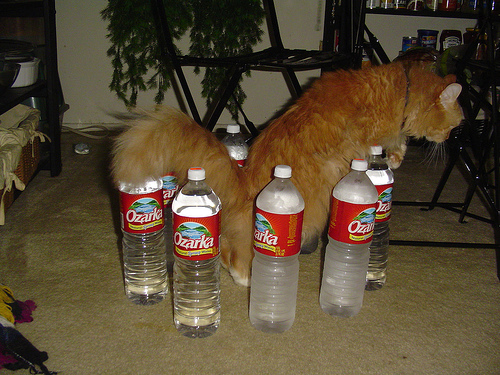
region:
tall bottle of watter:
[321, 158, 378, 320]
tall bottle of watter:
[362, 143, 389, 294]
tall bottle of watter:
[252, 163, 299, 335]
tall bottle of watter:
[169, 165, 226, 338]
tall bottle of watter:
[116, 160, 168, 302]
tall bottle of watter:
[213, 123, 246, 167]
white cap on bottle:
[349, 155, 370, 174]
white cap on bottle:
[271, 162, 295, 180]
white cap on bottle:
[184, 165, 209, 183]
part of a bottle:
[341, 297, 347, 305]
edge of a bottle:
[273, 305, 274, 306]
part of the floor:
[253, 327, 303, 362]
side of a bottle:
[241, 281, 253, 291]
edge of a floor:
[377, 311, 382, 334]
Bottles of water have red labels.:
[159, 155, 384, 346]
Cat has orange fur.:
[101, 44, 496, 295]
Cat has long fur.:
[95, 33, 483, 299]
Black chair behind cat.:
[135, 1, 418, 208]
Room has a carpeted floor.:
[37, 88, 498, 374]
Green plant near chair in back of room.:
[58, 2, 298, 137]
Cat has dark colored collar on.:
[288, 24, 485, 256]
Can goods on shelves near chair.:
[305, 1, 498, 188]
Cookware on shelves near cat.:
[0, 5, 89, 232]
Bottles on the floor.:
[113, 120, 393, 342]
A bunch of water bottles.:
[116, 123, 396, 340]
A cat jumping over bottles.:
[109, 58, 466, 288]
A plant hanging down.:
[98, 0, 269, 127]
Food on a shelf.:
[363, 0, 497, 55]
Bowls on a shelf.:
[0, 36, 42, 93]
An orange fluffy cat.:
[101, 58, 465, 290]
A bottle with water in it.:
[170, 166, 224, 341]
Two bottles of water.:
[248, 156, 379, 336]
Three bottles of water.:
[170, 156, 378, 341]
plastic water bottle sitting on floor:
[169, 166, 227, 342]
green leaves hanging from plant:
[102, 0, 172, 111]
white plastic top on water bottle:
[268, 161, 295, 180]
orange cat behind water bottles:
[109, 58, 473, 325]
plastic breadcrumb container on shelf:
[415, 20, 442, 55]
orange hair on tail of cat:
[109, 108, 202, 188]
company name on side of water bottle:
[171, 215, 222, 261]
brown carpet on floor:
[394, 257, 497, 353]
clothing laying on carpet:
[4, 284, 49, 373]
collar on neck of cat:
[395, 59, 415, 127]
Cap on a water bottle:
[181, 165, 208, 185]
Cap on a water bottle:
[269, 161, 294, 181]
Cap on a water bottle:
[346, 155, 370, 175]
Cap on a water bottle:
[365, 139, 387, 159]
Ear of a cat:
[436, 77, 466, 110]